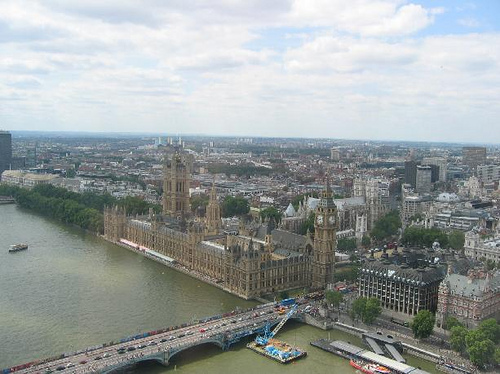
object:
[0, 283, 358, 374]
bridge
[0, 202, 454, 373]
river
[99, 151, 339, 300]
castle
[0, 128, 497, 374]
city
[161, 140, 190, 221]
tower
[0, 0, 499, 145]
sky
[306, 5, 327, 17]
clouds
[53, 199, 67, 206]
bushes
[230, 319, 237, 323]
cars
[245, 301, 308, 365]
barge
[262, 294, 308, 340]
crane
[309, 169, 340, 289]
building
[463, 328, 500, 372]
trees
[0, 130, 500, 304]
background